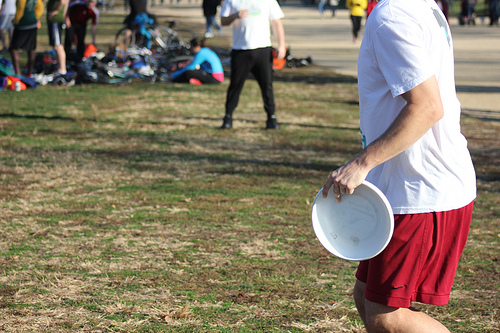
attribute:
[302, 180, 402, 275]
frisbee — white, round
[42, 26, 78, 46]
white — frisbee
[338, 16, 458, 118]
man — moving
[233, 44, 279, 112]
man's pants — black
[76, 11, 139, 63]
people — sitting down